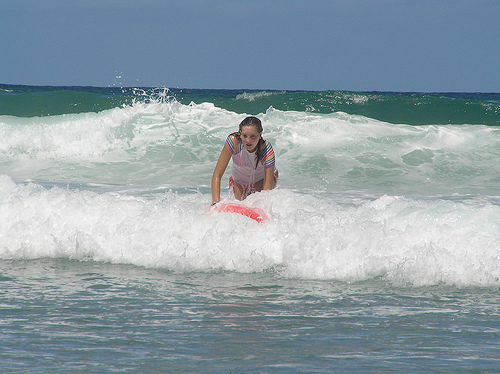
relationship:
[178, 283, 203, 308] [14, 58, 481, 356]
ripples in water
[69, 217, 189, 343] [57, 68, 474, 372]
ripples in water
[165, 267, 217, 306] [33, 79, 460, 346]
ripples in water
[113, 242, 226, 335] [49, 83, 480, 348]
ripples in water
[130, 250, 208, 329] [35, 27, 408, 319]
ripples in water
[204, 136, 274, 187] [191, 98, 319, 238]
stripes of shirt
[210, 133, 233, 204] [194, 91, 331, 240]
arm of girl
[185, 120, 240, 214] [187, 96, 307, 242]
arm of girl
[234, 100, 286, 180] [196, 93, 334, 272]
forehead of girl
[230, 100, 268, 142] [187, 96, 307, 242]
hair of girl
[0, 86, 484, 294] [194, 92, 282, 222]
wave in front of girl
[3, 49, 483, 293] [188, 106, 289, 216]
wave behind girl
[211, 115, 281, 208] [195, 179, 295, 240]
female on surf board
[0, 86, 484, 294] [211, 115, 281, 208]
wave behind female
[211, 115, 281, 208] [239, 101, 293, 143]
female with hair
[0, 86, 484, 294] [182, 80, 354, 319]
wave behind surfer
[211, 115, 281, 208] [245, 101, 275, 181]
female with hair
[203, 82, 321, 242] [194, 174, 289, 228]
female on board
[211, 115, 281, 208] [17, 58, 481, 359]
female in ocean